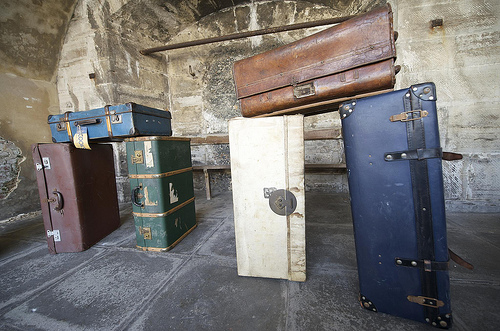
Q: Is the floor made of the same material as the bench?
A: No, the floor is made of concrete and the bench is made of wood.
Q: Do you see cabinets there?
A: No, there are no cabinets.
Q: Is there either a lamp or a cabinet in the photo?
A: No, there are no cabinets or lamps.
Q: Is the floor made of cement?
A: Yes, the floor is made of cement.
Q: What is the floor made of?
A: The floor is made of concrete.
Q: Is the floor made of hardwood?
A: No, the floor is made of concrete.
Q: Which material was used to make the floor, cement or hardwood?
A: The floor is made of cement.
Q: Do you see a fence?
A: No, there are no fences.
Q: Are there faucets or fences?
A: No, there are no fences or faucets.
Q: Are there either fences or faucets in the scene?
A: No, there are no fences or faucets.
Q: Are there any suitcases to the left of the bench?
A: Yes, there is a suitcase to the left of the bench.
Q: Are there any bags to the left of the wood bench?
A: No, there is a suitcase to the left of the bench.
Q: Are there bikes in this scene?
A: No, there are no bikes.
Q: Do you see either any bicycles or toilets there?
A: No, there are no bicycles or toilets.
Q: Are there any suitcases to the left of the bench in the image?
A: Yes, there is a suitcase to the left of the bench.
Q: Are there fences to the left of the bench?
A: No, there is a suitcase to the left of the bench.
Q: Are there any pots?
A: No, there are no pots.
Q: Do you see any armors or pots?
A: No, there are no pots or armors.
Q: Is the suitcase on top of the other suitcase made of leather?
A: Yes, the suitcase is made of leather.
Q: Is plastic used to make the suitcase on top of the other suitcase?
A: No, the suitcase is made of leather.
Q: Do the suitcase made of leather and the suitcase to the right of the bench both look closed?
A: Yes, both the suitcase and the suitcase are closed.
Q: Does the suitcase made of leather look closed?
A: Yes, the suitcase is closed.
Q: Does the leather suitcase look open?
A: No, the suitcase is closed.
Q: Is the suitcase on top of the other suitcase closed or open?
A: The suitcase is closed.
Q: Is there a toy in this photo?
A: No, there are no toys.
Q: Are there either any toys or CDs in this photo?
A: No, there are no toys or cds.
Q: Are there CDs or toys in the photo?
A: No, there are no toys or cds.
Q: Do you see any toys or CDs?
A: No, there are no toys or cds.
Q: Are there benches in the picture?
A: Yes, there is a bench.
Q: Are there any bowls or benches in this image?
A: Yes, there is a bench.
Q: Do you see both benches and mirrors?
A: No, there is a bench but no mirrors.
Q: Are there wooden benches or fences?
A: Yes, there is a wood bench.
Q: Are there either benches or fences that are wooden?
A: Yes, the bench is wooden.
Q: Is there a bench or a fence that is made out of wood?
A: Yes, the bench is made of wood.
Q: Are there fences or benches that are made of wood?
A: Yes, the bench is made of wood.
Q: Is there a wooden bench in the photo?
A: Yes, there is a wood bench.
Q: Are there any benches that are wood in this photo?
A: Yes, there is a wood bench.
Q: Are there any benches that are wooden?
A: Yes, there is a bench that is wooden.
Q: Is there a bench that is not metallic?
A: Yes, there is a wooden bench.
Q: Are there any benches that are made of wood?
A: Yes, there is a bench that is made of wood.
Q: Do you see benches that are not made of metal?
A: Yes, there is a bench that is made of wood.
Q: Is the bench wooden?
A: Yes, the bench is wooden.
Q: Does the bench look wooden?
A: Yes, the bench is wooden.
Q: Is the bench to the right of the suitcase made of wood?
A: Yes, the bench is made of wood.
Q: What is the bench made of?
A: The bench is made of wood.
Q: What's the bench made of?
A: The bench is made of wood.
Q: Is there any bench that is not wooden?
A: No, there is a bench but it is wooden.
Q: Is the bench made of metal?
A: No, the bench is made of wood.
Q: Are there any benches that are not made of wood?
A: No, there is a bench but it is made of wood.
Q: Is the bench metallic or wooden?
A: The bench is wooden.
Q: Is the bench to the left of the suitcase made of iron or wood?
A: The bench is made of wood.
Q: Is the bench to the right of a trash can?
A: No, the bench is to the right of the suitcase.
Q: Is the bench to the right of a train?
A: No, the bench is to the right of the suitcase.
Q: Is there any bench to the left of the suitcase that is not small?
A: Yes, there is a bench to the left of the suitcase.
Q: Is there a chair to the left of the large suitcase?
A: No, there is a bench to the left of the suitcase.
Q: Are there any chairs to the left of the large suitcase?
A: No, there is a bench to the left of the suitcase.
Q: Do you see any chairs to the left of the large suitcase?
A: No, there is a bench to the left of the suitcase.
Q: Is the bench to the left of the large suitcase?
A: Yes, the bench is to the left of the suitcase.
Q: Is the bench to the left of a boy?
A: No, the bench is to the left of the suitcase.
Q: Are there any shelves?
A: No, there are no shelves.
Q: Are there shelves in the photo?
A: No, there are no shelves.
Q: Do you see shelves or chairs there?
A: No, there are no shelves or chairs.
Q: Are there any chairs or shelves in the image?
A: No, there are no shelves or chairs.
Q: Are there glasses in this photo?
A: No, there are no glasses.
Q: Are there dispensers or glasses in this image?
A: No, there are no glasses or dispensers.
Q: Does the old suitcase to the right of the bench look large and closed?
A: Yes, the suitcase is large and closed.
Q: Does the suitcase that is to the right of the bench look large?
A: Yes, the suitcase is large.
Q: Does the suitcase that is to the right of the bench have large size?
A: Yes, the suitcase is large.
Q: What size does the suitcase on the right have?
A: The suitcase has large size.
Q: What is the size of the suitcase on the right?
A: The suitcase is large.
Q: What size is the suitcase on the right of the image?
A: The suitcase is large.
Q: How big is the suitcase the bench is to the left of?
A: The suitcase is large.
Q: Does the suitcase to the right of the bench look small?
A: No, the suitcase is large.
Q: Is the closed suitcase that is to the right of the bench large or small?
A: The suitcase is large.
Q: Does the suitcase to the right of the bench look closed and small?
A: No, the suitcase is closed but large.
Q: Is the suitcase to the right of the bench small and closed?
A: No, the suitcase is closed but large.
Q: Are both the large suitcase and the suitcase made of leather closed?
A: Yes, both the suitcase and the suitcase are closed.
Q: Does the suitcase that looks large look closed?
A: Yes, the suitcase is closed.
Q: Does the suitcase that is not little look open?
A: No, the suitcase is closed.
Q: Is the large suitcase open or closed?
A: The suitcase is closed.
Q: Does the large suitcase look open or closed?
A: The suitcase is closed.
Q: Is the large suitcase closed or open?
A: The suitcase is closed.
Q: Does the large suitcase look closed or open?
A: The suitcase is closed.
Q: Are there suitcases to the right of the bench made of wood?
A: Yes, there is a suitcase to the right of the bench.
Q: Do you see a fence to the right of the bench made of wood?
A: No, there is a suitcase to the right of the bench.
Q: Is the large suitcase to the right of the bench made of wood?
A: Yes, the suitcase is to the right of the bench.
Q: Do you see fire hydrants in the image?
A: No, there are no fire hydrants.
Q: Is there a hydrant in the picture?
A: No, there are no fire hydrants.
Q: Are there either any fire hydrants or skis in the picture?
A: No, there are no fire hydrants or skis.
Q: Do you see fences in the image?
A: No, there are no fences.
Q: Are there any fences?
A: No, there are no fences.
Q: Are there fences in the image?
A: No, there are no fences.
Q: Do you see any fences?
A: No, there are no fences.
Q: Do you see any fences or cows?
A: No, there are no fences or cows.